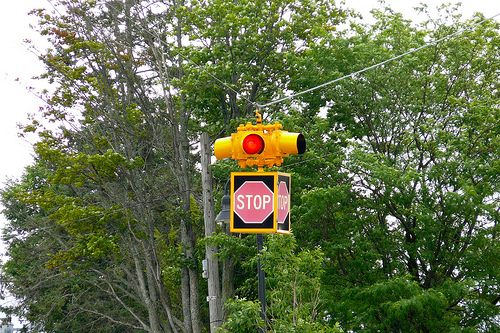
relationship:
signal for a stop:
[183, 100, 322, 271] [229, 174, 289, 224]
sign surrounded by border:
[234, 180, 273, 223] [268, 172, 294, 221]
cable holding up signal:
[283, 46, 387, 136] [214, 123, 306, 167]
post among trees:
[254, 227, 274, 331] [2, 0, 482, 330]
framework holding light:
[211, 106, 310, 169] [236, 130, 266, 158]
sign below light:
[234, 180, 273, 223] [239, 130, 267, 158]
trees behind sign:
[2, 0, 482, 330] [232, 172, 292, 230]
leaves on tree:
[354, 278, 450, 328] [287, 0, 484, 330]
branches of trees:
[113, 239, 202, 331] [2, 86, 347, 331]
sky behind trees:
[0, 2, 92, 184] [2, 0, 482, 330]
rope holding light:
[97, 0, 483, 109] [239, 130, 267, 158]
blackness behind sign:
[260, 172, 274, 187] [232, 179, 274, 223]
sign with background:
[234, 180, 273, 222] [232, 173, 275, 229]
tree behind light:
[164, 110, 401, 331] [239, 130, 266, 156]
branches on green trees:
[125, 184, 198, 330] [103, 0, 175, 332]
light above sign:
[241, 130, 267, 161] [231, 175, 273, 229]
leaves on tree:
[358, 146, 423, 195] [287, 0, 484, 330]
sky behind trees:
[335, 0, 484, 42] [2, 0, 482, 330]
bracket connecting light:
[209, 108, 319, 238] [65, 26, 411, 306]